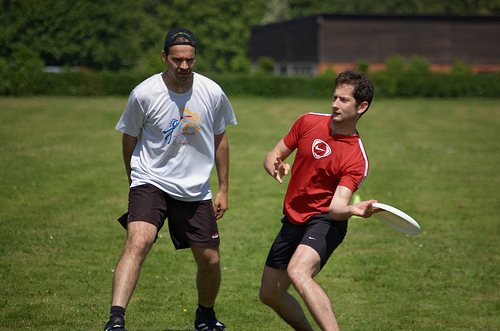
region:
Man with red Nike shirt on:
[283, 70, 416, 326]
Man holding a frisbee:
[268, 57, 420, 324]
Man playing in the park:
[255, 63, 447, 328]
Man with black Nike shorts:
[253, 63, 423, 320]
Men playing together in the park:
[41, 26, 431, 324]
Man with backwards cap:
[46, 23, 258, 325]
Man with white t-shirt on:
[85, 25, 247, 306]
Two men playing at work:
[55, 5, 462, 320]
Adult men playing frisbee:
[68, 19, 455, 318]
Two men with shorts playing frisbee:
[73, 20, 448, 324]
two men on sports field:
[36, 23, 453, 321]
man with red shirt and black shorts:
[261, 51, 439, 318]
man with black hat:
[103, 27, 247, 329]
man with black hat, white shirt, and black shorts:
[96, 14, 239, 329]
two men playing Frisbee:
[59, 41, 451, 314]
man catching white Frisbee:
[262, 66, 418, 325]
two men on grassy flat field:
[38, 31, 440, 321]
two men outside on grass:
[63, 26, 448, 310]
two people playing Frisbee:
[75, 26, 439, 296]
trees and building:
[9, 13, 486, 109]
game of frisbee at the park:
[101, 15, 443, 327]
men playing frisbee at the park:
[89, 17, 366, 316]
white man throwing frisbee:
[258, 40, 424, 330]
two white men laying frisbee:
[117, 19, 404, 325]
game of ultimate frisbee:
[124, 23, 436, 312]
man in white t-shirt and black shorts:
[114, 10, 243, 326]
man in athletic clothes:
[270, 50, 372, 329]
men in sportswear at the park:
[101, 29, 377, 327]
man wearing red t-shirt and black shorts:
[246, 48, 434, 329]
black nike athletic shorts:
[254, 183, 359, 303]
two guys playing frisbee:
[98, 24, 422, 329]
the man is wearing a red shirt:
[282, 109, 367, 229]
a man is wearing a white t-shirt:
[112, 66, 236, 204]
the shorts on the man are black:
[125, 177, 222, 249]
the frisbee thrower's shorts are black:
[263, 189, 428, 275]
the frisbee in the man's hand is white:
[371, 195, 421, 236]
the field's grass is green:
[3, 94, 496, 326]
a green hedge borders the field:
[4, 67, 496, 99]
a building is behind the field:
[242, 7, 497, 86]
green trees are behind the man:
[3, 1, 265, 78]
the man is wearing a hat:
[154, 26, 205, 60]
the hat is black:
[162, 27, 197, 52]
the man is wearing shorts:
[258, 207, 354, 274]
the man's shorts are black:
[113, 177, 233, 262]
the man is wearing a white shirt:
[113, 69, 240, 204]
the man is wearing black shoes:
[87, 304, 235, 329]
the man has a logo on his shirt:
[307, 133, 334, 163]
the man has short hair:
[333, 58, 376, 122]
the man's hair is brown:
[331, 67, 375, 119]